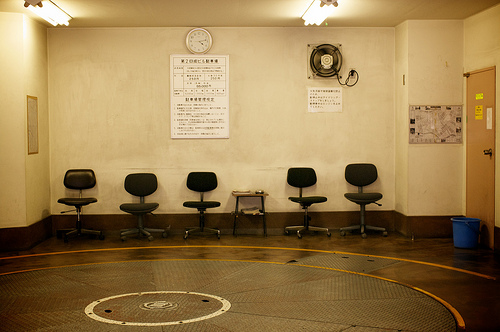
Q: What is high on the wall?
A: Clock.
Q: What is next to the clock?
A: Fan.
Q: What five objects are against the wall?
A: Chairs.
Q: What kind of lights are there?
A: Florescent lights.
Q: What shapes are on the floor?
A: Circles.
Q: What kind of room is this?
A: Waiting.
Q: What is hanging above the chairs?
A: Chart.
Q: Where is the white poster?
A: Hanging on the wall.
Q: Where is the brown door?
A: On the right side of the room.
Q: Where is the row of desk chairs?
A: Lined up to the wall.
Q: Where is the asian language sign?
A: On the wall.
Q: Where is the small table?
A: By the wall.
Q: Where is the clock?
A: On the wall.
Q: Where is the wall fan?
A: On the wall.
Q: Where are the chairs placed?
A: Up against the wall.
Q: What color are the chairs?
A: Black.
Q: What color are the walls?
A: Cream white.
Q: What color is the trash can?
A: Blue.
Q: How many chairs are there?
A: Five.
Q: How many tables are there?
A: One.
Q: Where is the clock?
A: On the wall.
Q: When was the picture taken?
A: 4:15.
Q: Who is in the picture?
A: No one.